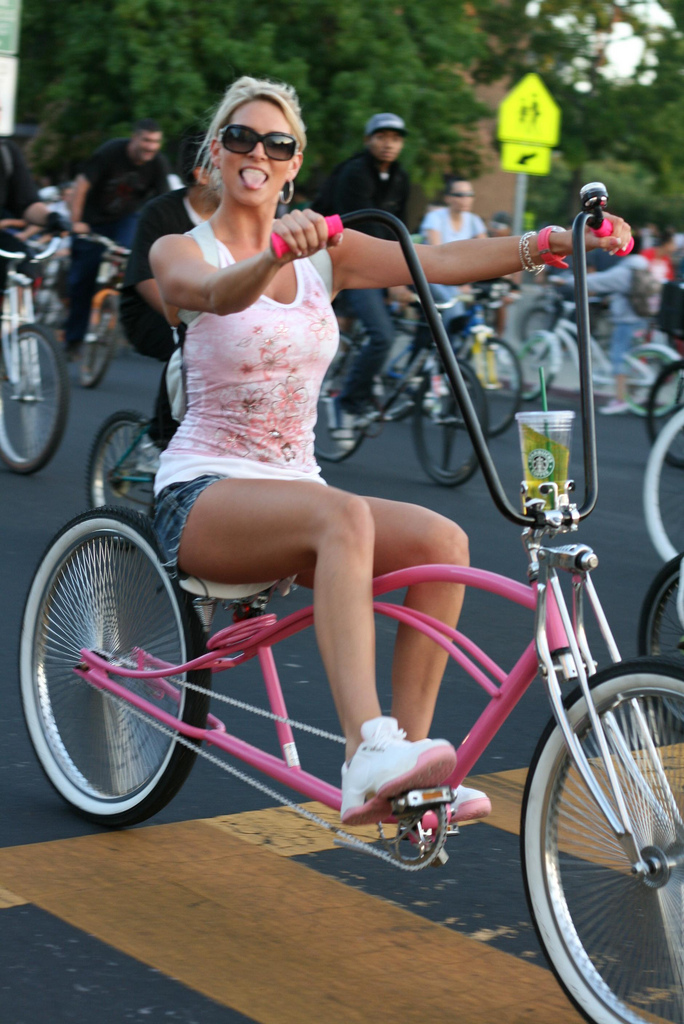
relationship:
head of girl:
[205, 88, 304, 207] [146, 68, 494, 837]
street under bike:
[4, 324, 677, 1020] [13, 177, 680, 1020]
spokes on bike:
[546, 687, 682, 1009] [13, 177, 680, 1020]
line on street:
[14, 820, 680, 1022] [4, 324, 677, 1020]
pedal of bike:
[384, 788, 455, 811] [13, 177, 680, 1020]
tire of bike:
[17, 505, 214, 828] [13, 177, 680, 1020]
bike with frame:
[13, 177, 680, 1020] [81, 564, 571, 837]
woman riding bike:
[145, 76, 488, 822] [13, 177, 680, 1020]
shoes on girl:
[340, 716, 456, 826] [146, 68, 494, 837]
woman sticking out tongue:
[145, 76, 488, 822] [236, 157, 277, 191]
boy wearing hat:
[316, 112, 415, 421] [360, 112, 414, 141]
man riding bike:
[53, 122, 182, 348] [44, 214, 132, 386]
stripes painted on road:
[9, 819, 560, 1022] [9, 326, 680, 1019]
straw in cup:
[536, 367, 555, 471] [508, 413, 570, 511]